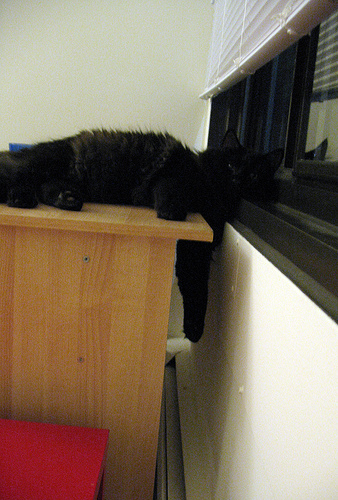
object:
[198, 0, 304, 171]
window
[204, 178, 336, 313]
window ledge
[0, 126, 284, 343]
cat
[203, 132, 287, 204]
head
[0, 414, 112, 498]
chair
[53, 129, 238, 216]
fur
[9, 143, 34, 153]
object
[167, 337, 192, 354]
vent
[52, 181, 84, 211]
foot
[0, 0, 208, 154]
wall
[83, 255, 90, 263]
screw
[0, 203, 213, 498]
desk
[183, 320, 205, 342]
paw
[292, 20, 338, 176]
window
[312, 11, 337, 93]
blinds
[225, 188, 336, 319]
sill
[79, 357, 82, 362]
screw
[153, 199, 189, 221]
paw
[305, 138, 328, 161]
ear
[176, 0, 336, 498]
wall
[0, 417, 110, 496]
table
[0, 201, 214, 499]
dresser